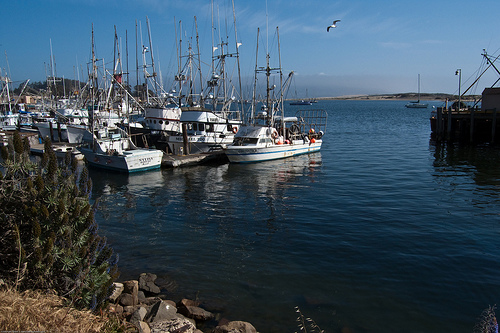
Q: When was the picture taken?
A: Daytime.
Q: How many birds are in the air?
A: One.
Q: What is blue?
A: Sky.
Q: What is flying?
A: A bird.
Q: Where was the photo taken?
A: Near the water.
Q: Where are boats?
A: In the water.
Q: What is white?
A: Boats.